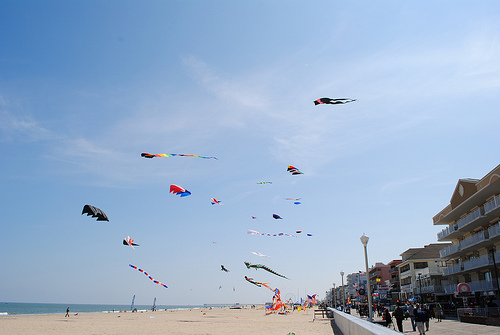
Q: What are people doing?
A: Flying kites.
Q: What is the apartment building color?
A: Brown.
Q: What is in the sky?
A: Many kites.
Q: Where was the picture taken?
A: Beach.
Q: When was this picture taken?
A: On a sunny day.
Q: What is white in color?
A: Clouds.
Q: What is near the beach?
A: Condo.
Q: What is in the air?
A: Kites.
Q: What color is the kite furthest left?
A: Black.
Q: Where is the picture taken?
A: Beach.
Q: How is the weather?
A: Mostly clear.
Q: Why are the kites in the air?
A: Wind.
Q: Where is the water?
A: To the left.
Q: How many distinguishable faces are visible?
A: Zero.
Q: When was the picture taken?
A: Daytime.